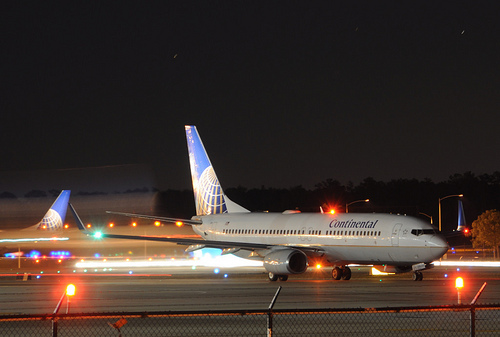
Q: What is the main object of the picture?
A: An airplane.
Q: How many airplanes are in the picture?
A: Two.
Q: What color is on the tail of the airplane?
A: Blue.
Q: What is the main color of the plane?
A: White.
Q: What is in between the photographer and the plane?
A: A fence.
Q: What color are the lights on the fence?
A: Orange.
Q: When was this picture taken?
A: At night time.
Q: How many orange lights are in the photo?
A: 12.